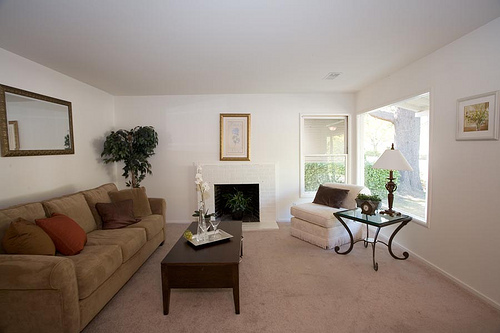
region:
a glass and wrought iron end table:
[333, 194, 412, 271]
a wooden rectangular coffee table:
[156, 212, 248, 314]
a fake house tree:
[91, 115, 167, 192]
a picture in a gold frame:
[206, 107, 257, 160]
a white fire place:
[187, 159, 280, 229]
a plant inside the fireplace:
[218, 191, 255, 219]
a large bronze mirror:
[0, 79, 80, 162]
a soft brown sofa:
[11, 173, 168, 330]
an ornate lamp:
[371, 141, 411, 226]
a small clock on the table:
[357, 198, 375, 215]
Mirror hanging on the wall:
[1, 72, 80, 164]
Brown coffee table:
[158, 203, 260, 314]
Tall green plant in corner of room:
[97, 122, 169, 187]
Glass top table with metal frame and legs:
[327, 196, 428, 270]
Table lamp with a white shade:
[368, 140, 417, 216]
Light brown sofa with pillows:
[2, 170, 169, 330]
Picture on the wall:
[207, 101, 260, 162]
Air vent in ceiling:
[319, 67, 349, 90]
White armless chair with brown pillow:
[288, 173, 371, 251]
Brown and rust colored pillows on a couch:
[5, 213, 95, 257]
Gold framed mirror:
[0, 82, 84, 160]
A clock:
[352, 196, 384, 224]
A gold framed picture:
[211, 108, 255, 160]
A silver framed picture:
[448, 96, 498, 150]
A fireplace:
[192, 161, 292, 232]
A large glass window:
[348, 89, 440, 233]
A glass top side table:
[319, 173, 421, 276]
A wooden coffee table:
[155, 172, 255, 322]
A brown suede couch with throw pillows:
[0, 132, 193, 329]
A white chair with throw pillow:
[279, 154, 377, 254]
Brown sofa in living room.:
[2, 182, 167, 329]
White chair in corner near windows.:
[283, 179, 370, 256]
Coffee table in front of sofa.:
[153, 211, 254, 325]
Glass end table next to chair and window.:
[332, 198, 418, 274]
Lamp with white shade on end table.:
[371, 140, 417, 217]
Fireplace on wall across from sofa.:
[186, 158, 291, 237]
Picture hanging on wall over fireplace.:
[208, 106, 260, 161]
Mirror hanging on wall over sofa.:
[1, 83, 76, 162]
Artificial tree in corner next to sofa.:
[98, 123, 166, 200]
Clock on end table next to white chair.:
[354, 197, 381, 222]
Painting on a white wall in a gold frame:
[212, 106, 260, 163]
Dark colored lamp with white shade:
[370, 137, 412, 217]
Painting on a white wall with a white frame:
[435, 90, 498, 143]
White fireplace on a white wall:
[191, 158, 282, 225]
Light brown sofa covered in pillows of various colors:
[4, 182, 173, 328]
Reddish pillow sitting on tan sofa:
[33, 204, 93, 256]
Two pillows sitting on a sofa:
[83, 181, 155, 231]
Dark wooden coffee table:
[158, 207, 245, 318]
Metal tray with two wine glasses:
[181, 222, 235, 253]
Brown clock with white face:
[353, 195, 377, 216]